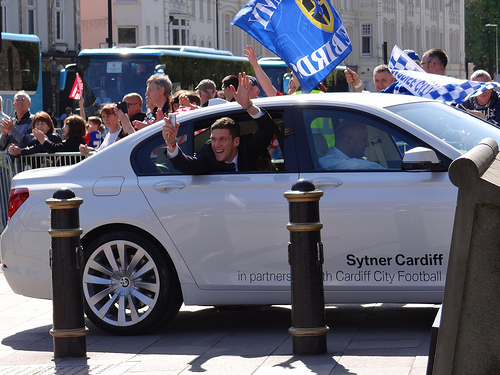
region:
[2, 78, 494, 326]
silver four door sedan with two men inside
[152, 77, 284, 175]
adult male in black jacket waving to crowd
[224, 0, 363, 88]
blue flag a spectator is holding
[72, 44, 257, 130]
passenger bus on city street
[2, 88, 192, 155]
crowd behind fence during a parade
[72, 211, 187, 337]
black car tire with silver rims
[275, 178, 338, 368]
brown and gold pole on sidewalk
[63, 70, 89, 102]
red and white flag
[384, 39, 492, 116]
blue and white checkered banner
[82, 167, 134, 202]
gas tank door on silver car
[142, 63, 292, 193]
The man is waving.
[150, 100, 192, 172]
The man is holding a phone in his hand.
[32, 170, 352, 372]
Two black and gold barriers.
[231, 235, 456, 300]
Writing on the side of the car.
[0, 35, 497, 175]
A large group of people in the background.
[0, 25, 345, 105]
Three large busses.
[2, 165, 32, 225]
A brake light.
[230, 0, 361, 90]
A large blue flag.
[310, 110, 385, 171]
The car's driver.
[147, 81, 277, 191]
The man is wearing a suit.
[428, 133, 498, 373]
An end of a gray object standing on the sidewalk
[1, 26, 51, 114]
The end of a blue bus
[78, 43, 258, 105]
A bus on the street in the background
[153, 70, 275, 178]
Man waving and taking a selfie from a car window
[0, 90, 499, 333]
A white car with passengers parked on the street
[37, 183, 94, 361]
A black post on the sidewalk with gold trim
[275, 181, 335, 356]
Another black post trimmed in gold on the sidewalk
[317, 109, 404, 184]
A man sitting in front seat on the passenger side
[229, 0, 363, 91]
Someone holding a flag in the air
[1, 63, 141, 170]
A group of people standing behind a silver gate in the background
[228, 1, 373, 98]
a blue flag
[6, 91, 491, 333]
a white four door car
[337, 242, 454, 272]
a persons name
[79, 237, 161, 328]
silver rims on the car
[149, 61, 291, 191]
man in suit hanging out car window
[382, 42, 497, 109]
a blue and white checkered flag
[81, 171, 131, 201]
where you put gas in a car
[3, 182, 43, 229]
a red tail light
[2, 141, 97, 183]
a metal fence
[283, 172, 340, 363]
a black and gold pole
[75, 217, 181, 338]
car tire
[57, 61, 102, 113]
red flag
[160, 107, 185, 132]
cell phone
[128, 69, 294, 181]
man in a suit holding his hands up and smiling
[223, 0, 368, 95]
blue flag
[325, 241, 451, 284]
black text on a white car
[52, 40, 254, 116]
a big bus in the background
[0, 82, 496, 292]
a four door white car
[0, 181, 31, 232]
red car light on the right side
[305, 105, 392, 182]
man wearing a long sleeved white shirt